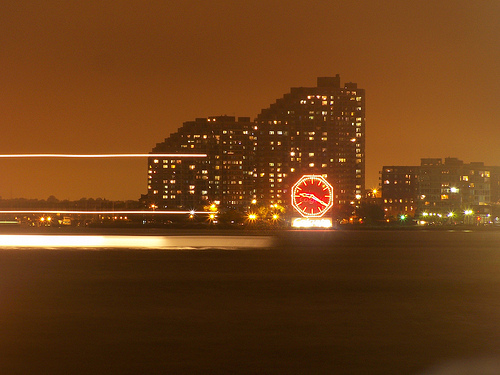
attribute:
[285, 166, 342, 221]
clock — big, illuminated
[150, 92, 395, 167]
buildings — tall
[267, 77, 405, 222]
building — tall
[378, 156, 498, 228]
building — small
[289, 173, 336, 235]
clock — big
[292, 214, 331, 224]
lights — on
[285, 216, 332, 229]
light — rectangular